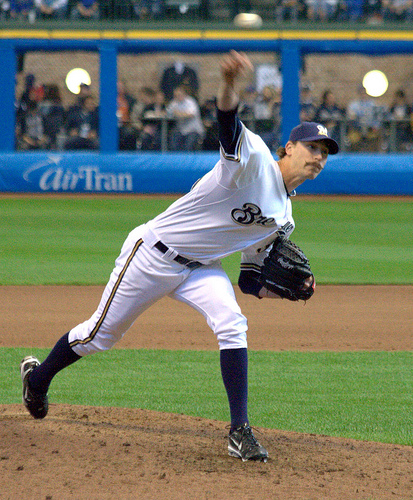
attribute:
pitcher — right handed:
[17, 50, 345, 463]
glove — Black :
[254, 235, 320, 307]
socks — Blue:
[218, 354, 249, 424]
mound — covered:
[10, 386, 412, 497]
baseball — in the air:
[234, 9, 267, 40]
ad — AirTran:
[20, 155, 133, 195]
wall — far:
[0, 152, 413, 196]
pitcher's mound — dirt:
[1, 404, 411, 497]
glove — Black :
[237, 225, 324, 307]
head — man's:
[294, 141, 330, 184]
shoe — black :
[206, 425, 280, 473]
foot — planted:
[226, 422, 269, 462]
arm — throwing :
[208, 38, 267, 170]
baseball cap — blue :
[286, 110, 343, 157]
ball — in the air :
[226, 9, 268, 30]